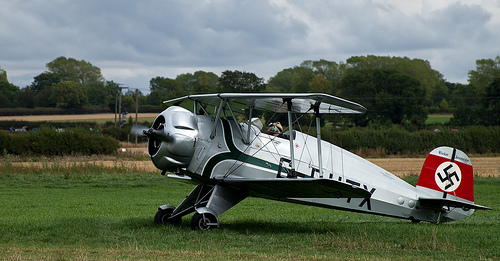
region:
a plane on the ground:
[141, 51, 432, 254]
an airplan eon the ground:
[154, 27, 342, 247]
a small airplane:
[155, 41, 325, 226]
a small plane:
[132, 112, 357, 248]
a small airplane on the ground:
[147, 78, 324, 248]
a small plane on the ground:
[107, 59, 369, 246]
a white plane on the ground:
[136, 84, 306, 248]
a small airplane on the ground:
[168, 68, 445, 254]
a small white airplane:
[177, 50, 435, 242]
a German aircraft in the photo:
[44, 32, 497, 231]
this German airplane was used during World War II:
[108, 67, 492, 241]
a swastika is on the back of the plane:
[402, 148, 485, 214]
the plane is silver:
[126, 71, 416, 240]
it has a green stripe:
[204, 122, 331, 178]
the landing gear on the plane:
[144, 181, 250, 237]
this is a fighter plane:
[115, 75, 490, 242]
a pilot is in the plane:
[242, 109, 289, 143]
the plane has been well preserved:
[132, 81, 481, 241]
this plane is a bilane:
[154, 78, 388, 203]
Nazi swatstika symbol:
[425, 163, 468, 192]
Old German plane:
[129, 83, 486, 250]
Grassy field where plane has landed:
[4, 151, 496, 256]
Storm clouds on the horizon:
[0, 1, 497, 81]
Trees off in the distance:
[1, 68, 497, 135]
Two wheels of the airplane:
[142, 193, 232, 236]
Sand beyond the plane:
[5, 147, 499, 179]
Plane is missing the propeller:
[137, 111, 194, 159]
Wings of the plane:
[162, 81, 355, 211]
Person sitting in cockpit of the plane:
[244, 116, 295, 143]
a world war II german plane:
[56, 58, 492, 256]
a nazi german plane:
[97, 43, 492, 256]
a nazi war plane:
[107, 66, 489, 247]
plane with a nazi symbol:
[87, 65, 496, 254]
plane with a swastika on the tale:
[109, 78, 499, 253]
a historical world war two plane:
[82, 78, 498, 245]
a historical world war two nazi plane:
[84, 53, 489, 251]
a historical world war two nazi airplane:
[64, 52, 490, 249]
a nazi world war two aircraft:
[75, 18, 492, 257]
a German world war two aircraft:
[92, 50, 498, 248]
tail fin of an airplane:
[416, 144, 483, 206]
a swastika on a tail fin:
[422, 153, 472, 197]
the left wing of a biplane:
[234, 88, 364, 118]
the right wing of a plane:
[164, 92, 228, 114]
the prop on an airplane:
[129, 104, 194, 164]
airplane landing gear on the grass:
[158, 194, 227, 229]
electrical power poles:
[109, 79, 151, 112]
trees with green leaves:
[362, 55, 404, 100]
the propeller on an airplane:
[129, 120, 173, 146]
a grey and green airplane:
[116, 63, 486, 231]